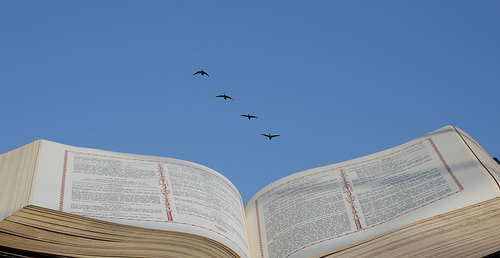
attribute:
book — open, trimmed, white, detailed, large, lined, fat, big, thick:
[2, 123, 500, 256]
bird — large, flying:
[189, 67, 283, 144]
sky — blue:
[0, 1, 499, 157]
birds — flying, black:
[190, 65, 293, 148]